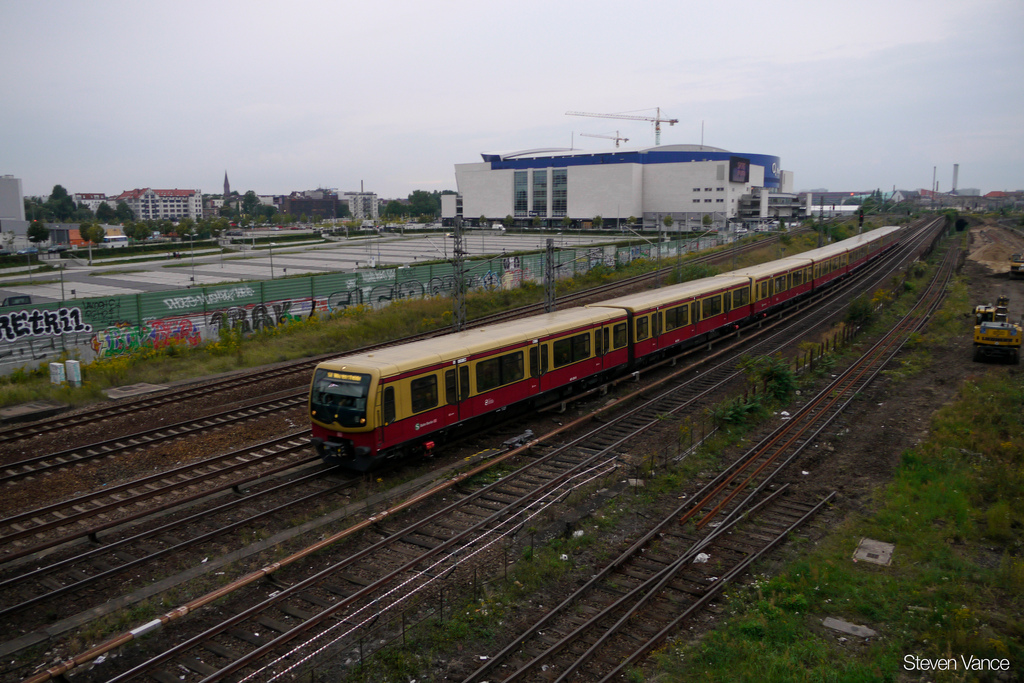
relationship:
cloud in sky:
[0, 0, 1024, 190] [699, 19, 909, 136]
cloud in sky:
[325, 0, 346, 65] [10, 8, 1015, 197]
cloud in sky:
[0, 0, 1024, 190] [10, 8, 1015, 197]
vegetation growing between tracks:
[29, 200, 1021, 674] [79, 208, 965, 680]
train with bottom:
[310, 224, 902, 470] [310, 235, 905, 467]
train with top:
[802, 238, 857, 293] [327, 216, 894, 428]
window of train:
[307, 358, 374, 432] [308, 224, 929, 479]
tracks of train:
[0, 219, 820, 555] [308, 224, 929, 479]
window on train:
[407, 372, 445, 412] [308, 224, 929, 479]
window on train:
[470, 348, 531, 390] [308, 194, 957, 478]